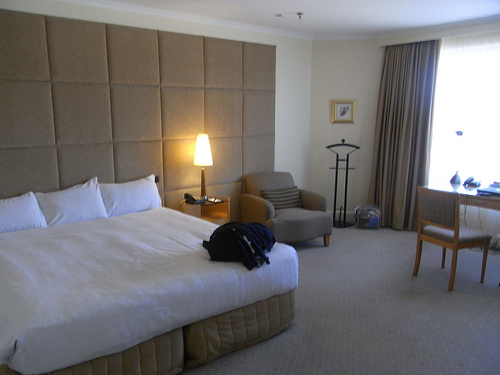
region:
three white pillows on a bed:
[1, 168, 162, 235]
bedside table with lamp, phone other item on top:
[179, 129, 229, 219]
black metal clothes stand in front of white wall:
[320, 133, 362, 231]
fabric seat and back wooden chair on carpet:
[410, 182, 492, 294]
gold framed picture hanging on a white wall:
[325, 95, 359, 127]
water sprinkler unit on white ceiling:
[292, 10, 308, 21]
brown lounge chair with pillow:
[233, 168, 337, 250]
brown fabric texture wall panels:
[0, 7, 280, 231]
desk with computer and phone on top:
[420, 175, 498, 215]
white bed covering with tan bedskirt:
[2, 205, 302, 374]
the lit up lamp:
[189, 131, 213, 196]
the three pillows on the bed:
[1, 178, 164, 221]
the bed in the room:
[5, 203, 304, 368]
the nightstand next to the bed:
[181, 187, 236, 227]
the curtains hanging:
[363, 34, 442, 235]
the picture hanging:
[329, 100, 359, 125]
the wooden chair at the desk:
[412, 184, 491, 293]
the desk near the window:
[423, 179, 499, 214]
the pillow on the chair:
[261, 185, 301, 209]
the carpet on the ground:
[146, 203, 498, 373]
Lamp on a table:
[184, 121, 221, 210]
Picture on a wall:
[317, 87, 367, 132]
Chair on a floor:
[403, 174, 496, 301]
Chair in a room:
[227, 155, 344, 255]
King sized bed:
[4, 159, 309, 364]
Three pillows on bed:
[1, 160, 194, 242]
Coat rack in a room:
[313, 134, 373, 236]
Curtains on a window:
[362, 37, 479, 240]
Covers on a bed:
[0, 170, 317, 341]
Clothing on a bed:
[179, 192, 306, 312]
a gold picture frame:
[329, 97, 357, 127]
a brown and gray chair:
[408, 183, 493, 294]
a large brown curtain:
[376, 38, 439, 236]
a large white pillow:
[38, 176, 107, 221]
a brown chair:
[241, 167, 332, 249]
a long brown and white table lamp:
[191, 123, 217, 198]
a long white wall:
[277, 45, 313, 193]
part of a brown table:
[451, 187, 496, 208]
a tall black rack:
[325, 132, 360, 232]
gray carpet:
[185, 225, 495, 374]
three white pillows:
[2, 173, 169, 227]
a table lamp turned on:
[189, 127, 219, 207]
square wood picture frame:
[325, 93, 358, 128]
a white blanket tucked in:
[2, 202, 295, 367]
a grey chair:
[236, 161, 337, 258]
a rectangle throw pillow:
[259, 178, 306, 213]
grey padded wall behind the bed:
[8, 5, 299, 274]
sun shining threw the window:
[412, 37, 497, 198]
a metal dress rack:
[316, 133, 365, 236]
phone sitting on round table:
[177, 185, 238, 225]